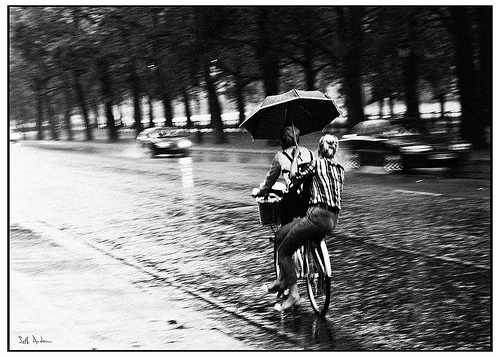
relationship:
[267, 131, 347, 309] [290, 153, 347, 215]
woman wearing shirt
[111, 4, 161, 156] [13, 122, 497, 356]
tree next to road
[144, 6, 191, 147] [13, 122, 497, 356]
tree next to road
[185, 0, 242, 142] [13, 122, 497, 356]
tree next to road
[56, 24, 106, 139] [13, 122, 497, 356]
tree next to road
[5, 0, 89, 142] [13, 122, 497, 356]
tree next to road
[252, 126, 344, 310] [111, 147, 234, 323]
people people riding bike down street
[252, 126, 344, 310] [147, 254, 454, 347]
people people riding bike in rain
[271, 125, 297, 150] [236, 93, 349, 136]
woman holding umbrella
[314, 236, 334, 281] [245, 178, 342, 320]
fender on bike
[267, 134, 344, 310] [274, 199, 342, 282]
woman wearing pants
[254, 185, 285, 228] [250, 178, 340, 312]
basket on bike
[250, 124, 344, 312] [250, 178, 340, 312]
people on bike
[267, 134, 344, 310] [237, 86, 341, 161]
woman holding umbrella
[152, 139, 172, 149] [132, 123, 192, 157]
headlight mounted on car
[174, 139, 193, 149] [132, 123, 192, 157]
headlight mounted on car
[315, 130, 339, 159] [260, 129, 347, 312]
hair belonging to woman